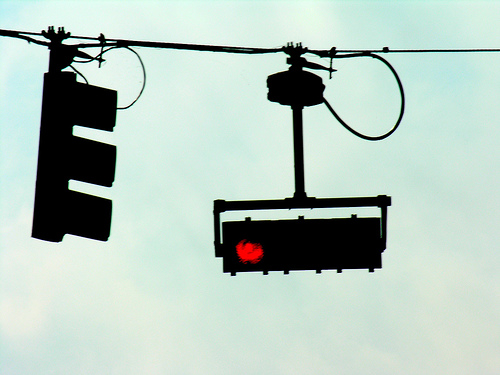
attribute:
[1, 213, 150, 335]
cloud — clear, blue, white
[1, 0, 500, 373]
sky — blue, clear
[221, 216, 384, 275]
traffic light — red, large, black, electrical, on, lit, horizontal, shiny, rectangle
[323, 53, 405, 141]
lines — black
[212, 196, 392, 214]
base — large, black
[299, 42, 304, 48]
screw — large, black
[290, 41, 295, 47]
screw — large, black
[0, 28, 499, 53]
electrical line — large, black, round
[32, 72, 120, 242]
traffic light — black, vertical